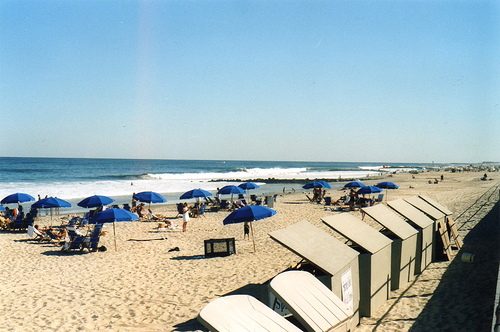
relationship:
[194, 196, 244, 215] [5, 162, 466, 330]
people on beach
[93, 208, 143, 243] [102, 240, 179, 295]
umbrella in sand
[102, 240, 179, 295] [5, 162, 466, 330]
sand on beach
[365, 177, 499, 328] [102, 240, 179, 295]
shadow on sand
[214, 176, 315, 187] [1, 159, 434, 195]
area in water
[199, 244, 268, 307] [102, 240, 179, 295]
footprints in sand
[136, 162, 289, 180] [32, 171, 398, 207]
waves hitting shore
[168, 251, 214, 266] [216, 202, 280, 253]
shadow of umbrella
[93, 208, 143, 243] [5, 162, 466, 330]
umbrella in beach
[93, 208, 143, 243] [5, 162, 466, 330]
umbrella on beach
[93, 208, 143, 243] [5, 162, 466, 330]
umbrella for beach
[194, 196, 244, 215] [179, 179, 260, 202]
people under umbrellas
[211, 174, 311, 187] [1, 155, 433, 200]
jetty in ocean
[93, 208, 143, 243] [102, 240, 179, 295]
umbrella on sand